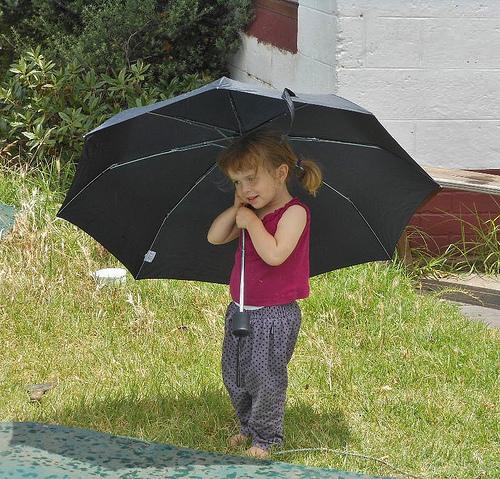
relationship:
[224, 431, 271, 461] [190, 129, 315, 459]
feet of girl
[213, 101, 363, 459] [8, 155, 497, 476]
girl in grass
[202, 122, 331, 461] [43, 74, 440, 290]
child holding an umbrella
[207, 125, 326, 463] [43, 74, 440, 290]
girl holds an umbrella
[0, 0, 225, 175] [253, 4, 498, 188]
bushes next to building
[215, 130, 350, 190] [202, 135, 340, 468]
hair of girl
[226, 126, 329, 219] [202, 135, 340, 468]
head of a girl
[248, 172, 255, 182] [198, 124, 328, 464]
eye of a girl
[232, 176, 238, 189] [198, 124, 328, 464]
eye of a girl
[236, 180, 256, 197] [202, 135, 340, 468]
nose of a girl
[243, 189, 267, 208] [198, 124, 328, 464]
mouth of a girl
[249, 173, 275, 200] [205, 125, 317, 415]
cheek of a girl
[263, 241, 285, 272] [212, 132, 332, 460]
elbow of girl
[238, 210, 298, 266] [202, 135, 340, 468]
arm of girl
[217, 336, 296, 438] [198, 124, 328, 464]
legs of girl